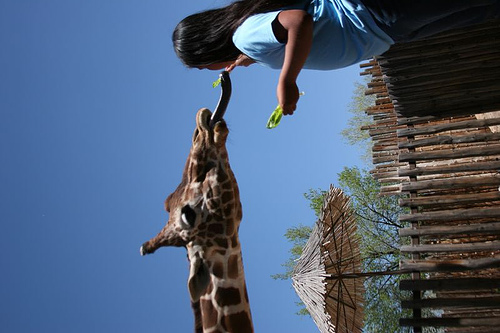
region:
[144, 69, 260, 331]
the giraffe is extending his neck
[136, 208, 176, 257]
the giraffe has horns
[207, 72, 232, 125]
the giraffe is sticking out his tongue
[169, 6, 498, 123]
the girl is feeding the giraffe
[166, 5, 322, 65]
the little girl has long hair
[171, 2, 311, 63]
the girls hair is long and straight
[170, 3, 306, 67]
the girl's hair is black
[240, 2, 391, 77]
the girl is wearing a short sleeve shirt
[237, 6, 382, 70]
the girl's shirt is blue in color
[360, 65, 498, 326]
a fence is running across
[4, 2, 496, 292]
The photo is sideways.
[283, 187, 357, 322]
The umbrella is made of straw.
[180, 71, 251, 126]
His tongue is long.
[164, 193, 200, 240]
The eye is black.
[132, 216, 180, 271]
The horn is brown.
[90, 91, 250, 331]
The giraffe is spotted.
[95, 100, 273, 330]
The giraffe is brown.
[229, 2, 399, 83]
The girl is wearing a blue shirt.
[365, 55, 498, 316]
The fence is wood.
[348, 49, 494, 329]
The fence is brown.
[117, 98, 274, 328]
this is a giraffe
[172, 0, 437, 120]
this is a person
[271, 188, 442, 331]
this is a shade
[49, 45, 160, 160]
the sky is very clear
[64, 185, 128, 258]
the sky is very clear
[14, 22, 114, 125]
the sky is very clear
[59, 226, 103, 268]
the sky is very clear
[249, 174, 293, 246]
the sky is very clear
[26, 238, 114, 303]
the sky is very clear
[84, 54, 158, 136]
the sky is very clear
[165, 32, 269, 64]
woman has black hair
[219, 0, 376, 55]
woman has blue shirt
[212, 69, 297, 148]
girl is holding lettuce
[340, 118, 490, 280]
wooden fence behind girl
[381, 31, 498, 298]
wooden fence is brown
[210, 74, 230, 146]
giraffe has long tongue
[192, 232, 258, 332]
brown and white spots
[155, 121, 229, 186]
giraffe has brown nose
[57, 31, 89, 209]
blue and clear sky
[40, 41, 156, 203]
no clouds in sky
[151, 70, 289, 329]
giraffe feeding from person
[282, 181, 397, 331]
umbrella over an area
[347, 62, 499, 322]
fence made from wood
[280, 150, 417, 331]
tree in the distance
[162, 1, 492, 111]
woman feeding the giraffe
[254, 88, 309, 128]
giraffe food in person's hand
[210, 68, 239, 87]
giraffe food on tongue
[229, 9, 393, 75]
shirt on the woman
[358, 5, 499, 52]
pants on the woman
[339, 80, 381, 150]
tree with colored leaves